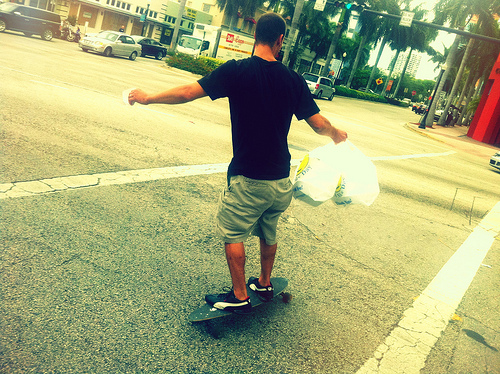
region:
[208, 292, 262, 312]
white stripe on black sneakers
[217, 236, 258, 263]
muscles on back of leg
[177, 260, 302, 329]
man balancing on green skate board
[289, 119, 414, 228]
white trash bag in man's hand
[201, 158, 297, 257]
man wearing green pants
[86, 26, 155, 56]
white car on the street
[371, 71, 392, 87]
large red and yellow sign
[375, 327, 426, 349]
broken lines on street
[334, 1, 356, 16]
green color on traffic post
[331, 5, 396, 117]
tall green palm trees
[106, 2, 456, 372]
he is riding a long board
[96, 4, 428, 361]
he is on a skateboard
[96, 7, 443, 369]
the man is on a skateboard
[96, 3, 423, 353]
he is crossing the street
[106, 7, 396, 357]
he's crossing the street on a skateboard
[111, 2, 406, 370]
he is holding plastic bags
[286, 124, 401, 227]
the bags are white and yellow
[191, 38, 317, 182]
his shirt is black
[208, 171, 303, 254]
he is wearing khaki shorts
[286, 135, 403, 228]
the bags have food containers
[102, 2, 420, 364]
man riding black skateboard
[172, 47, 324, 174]
man wearing black shirt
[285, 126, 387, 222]
man holding two bags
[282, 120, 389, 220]
yellow decal on bag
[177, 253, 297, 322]
man wearing black shoes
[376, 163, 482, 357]
white line on street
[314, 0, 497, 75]
traffic light on pole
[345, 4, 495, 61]
white sign on pole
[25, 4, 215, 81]
multiple cars on street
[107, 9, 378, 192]
man has arms extended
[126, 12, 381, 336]
man skateboarding on street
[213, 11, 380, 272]
man carrying two bags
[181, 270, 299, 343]
man's feet on skateboard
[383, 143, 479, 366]
white lines of crosswalk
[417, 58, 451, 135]
street light on corner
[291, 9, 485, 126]
trees lining the street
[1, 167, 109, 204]
cracks in the white paint of the crosswalk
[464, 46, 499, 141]
part of red structure on corner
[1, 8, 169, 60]
cars driving down the road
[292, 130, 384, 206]
two grocery bags in the persons hand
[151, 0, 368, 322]
the man is skateboarding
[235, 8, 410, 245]
man is carrying two bags